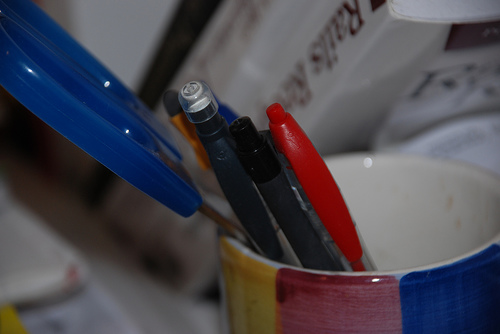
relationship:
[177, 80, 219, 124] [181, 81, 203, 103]
cap covers eraser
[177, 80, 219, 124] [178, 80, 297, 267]
cap on top of pencil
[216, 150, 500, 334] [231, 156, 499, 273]
coffee mug has mouth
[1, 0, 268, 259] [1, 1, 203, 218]
scissors have handle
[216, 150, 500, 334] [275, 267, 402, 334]
coffee mug has paint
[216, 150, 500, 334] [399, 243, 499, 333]
coffee mug has paint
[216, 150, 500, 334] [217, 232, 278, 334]
coffee mug has paint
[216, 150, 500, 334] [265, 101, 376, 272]
coffee mug holds pen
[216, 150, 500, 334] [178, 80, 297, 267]
coffee mug holds pencil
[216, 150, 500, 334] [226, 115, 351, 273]
coffee mug holds pen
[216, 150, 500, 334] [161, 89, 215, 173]
coffee mug holds pencil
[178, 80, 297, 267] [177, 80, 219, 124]
pencil has cap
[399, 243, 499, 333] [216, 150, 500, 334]
paint on outside of coffee mug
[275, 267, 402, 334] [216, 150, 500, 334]
paint on outside of coffee mug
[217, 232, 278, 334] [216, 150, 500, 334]
paint on outside of coffee mug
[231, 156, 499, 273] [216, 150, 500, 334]
inside of coffee mug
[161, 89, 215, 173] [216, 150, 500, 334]
pencil inside coffee mug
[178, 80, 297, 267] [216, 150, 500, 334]
pencil inside coffee mug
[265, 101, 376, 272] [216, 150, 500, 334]
pen inside coffee mug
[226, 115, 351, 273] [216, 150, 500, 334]
pen inside coffee mug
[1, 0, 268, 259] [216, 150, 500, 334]
scissors inside coffee mug